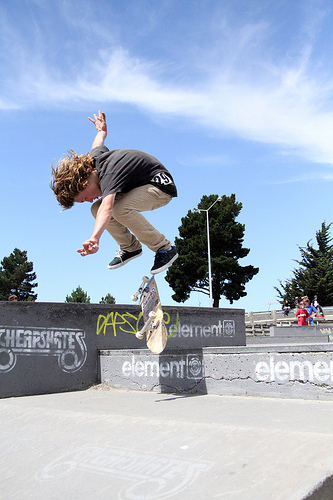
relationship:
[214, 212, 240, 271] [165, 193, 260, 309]
leaves on pine tree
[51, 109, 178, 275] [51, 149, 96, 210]
boy has hair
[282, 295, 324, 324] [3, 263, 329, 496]
people at skate park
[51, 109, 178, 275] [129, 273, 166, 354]
boy above skateboard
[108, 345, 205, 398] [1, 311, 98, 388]
logo on wall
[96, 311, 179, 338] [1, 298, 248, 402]
graffiti on wall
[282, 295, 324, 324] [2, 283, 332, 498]
people at skate park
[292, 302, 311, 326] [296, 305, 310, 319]
boy wearing shirt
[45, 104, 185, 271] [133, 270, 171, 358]
boy performing stunt on skateboard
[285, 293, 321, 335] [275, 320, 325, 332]
people on sidewalk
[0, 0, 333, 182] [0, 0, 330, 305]
cloud in sky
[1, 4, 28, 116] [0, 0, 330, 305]
cloud in sky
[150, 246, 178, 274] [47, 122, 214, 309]
shoe on boy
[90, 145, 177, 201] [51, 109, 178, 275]
black shirt on boy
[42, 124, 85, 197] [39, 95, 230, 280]
hair on boy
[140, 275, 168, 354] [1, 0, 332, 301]
flying skateboard in air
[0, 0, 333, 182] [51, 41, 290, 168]
cloud in sky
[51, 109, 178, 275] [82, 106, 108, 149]
boy has arm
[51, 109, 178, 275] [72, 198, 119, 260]
boy has arm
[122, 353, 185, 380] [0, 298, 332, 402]
word on wall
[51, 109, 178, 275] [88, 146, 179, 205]
boy wearing black shirt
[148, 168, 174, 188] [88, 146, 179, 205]
number on black shirt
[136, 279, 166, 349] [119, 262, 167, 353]
bottom of flying skateboard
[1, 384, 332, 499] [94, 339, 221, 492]
surface of skate ramp